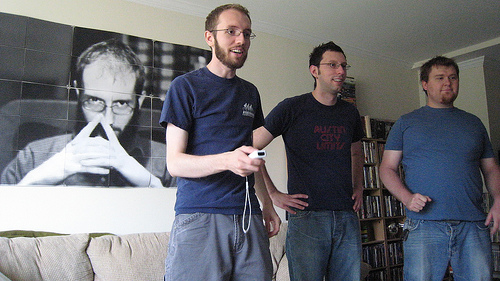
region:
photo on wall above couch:
[0, 1, 206, 279]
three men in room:
[160, 6, 498, 279]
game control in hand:
[217, 143, 268, 178]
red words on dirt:
[266, 93, 361, 210]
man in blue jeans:
[381, 54, 498, 279]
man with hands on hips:
[270, 41, 368, 279]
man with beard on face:
[207, 3, 256, 70]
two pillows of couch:
[0, 231, 169, 280]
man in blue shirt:
[380, 56, 497, 224]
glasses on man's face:
[206, 6, 258, 66]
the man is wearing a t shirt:
[166, 67, 267, 220]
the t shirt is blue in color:
[168, 70, 262, 223]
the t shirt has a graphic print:
[238, 101, 255, 116]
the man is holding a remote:
[248, 148, 266, 161]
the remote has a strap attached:
[241, 175, 253, 235]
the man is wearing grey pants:
[167, 208, 272, 278]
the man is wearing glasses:
[204, 24, 255, 37]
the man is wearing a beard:
[211, 32, 249, 68]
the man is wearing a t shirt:
[389, 104, 491, 219]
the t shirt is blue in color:
[387, 105, 499, 226]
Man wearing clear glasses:
[201, 3, 256, 74]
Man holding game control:
[161, 0, 272, 279]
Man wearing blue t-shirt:
[165, 6, 258, 209]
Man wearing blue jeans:
[280, 198, 362, 279]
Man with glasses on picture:
[0, 39, 172, 186]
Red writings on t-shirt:
[314, 123, 345, 156]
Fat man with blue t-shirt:
[380, 58, 499, 223]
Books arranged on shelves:
[363, 115, 407, 279]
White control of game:
[241, 145, 268, 238]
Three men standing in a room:
[166, 5, 496, 280]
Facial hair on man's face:
[202, 1, 255, 73]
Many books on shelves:
[350, 134, 409, 279]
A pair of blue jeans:
[398, 216, 498, 279]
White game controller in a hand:
[232, 140, 270, 235]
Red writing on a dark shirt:
[262, 92, 365, 212]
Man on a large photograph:
[0, 8, 217, 188]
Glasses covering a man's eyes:
[204, 19, 261, 46]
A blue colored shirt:
[382, 102, 497, 222]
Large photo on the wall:
[1, 8, 221, 199]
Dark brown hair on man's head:
[305, 37, 351, 95]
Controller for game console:
[247, 147, 268, 161]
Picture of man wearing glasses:
[65, 36, 149, 158]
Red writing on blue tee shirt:
[308, 121, 350, 156]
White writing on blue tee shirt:
[239, 99, 257, 119]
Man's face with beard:
[201, 2, 261, 72]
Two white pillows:
[2, 233, 175, 280]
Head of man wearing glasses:
[305, 39, 352, 101]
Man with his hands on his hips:
[264, 40, 373, 280]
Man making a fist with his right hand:
[377, 51, 497, 280]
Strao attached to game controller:
[240, 173, 255, 235]